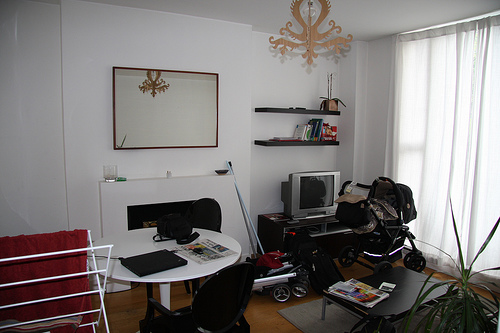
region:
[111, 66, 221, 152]
Mirror above the fireplace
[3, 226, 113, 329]
Towel drying on clothes rack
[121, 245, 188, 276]
Laptop on the table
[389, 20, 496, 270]
Drapes over the window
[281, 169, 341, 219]
Television on a stand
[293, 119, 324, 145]
Books on a shelf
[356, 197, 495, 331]
Green plant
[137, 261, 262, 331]
Chair pushed up to the table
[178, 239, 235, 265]
Newspaper on the table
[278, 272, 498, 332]
Rug on the floor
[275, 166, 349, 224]
silver and black tv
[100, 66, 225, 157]
picture in a brown frame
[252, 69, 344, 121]
black bookshelf with a plant on it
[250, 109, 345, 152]
books lined up on a bookshelf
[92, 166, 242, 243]
fireplace with a white mantle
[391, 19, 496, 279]
sliding glass door covered by a curtain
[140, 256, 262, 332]
chair with a black back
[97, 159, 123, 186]
small jar made of glass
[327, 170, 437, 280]
stroller sitting in the room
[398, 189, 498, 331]
large plant with green leaves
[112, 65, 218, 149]
a mirror on the wall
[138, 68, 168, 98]
object is reflecting in mirror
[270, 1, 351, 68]
object hanging from ceiling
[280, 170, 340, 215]
an old style TV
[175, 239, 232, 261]
newspaper on table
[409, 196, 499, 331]
thin green plant leaves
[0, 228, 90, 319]
the towel is red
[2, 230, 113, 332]
towel rack is white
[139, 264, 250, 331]
the chair is black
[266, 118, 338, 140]
stuff on a shelf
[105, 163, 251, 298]
A white and black fireplace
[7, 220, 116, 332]
A white foldable rack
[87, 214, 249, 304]
A round white table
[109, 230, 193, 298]
A closed laptop on a table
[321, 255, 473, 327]
A black coffee table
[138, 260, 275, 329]
A black desk chair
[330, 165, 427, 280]
A black baby stroller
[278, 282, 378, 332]
An area rug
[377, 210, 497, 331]
Part of a green houseplant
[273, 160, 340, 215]
A grey television turned off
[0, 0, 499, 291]
The walls and ceiling are painted white.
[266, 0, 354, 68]
A decorative light fixture hanging from the ceiling.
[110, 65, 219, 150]
A large mirror with a brown frame.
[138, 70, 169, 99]
A reflection of the light fixture in the mirror.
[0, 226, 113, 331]
A red blanket on a white blanket rack.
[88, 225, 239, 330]
A white table with a round top.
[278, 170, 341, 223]
A gray and black tube television set.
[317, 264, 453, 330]
A small wooden table with metal legs.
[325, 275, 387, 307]
A magazine on the corner of the table.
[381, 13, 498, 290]
Long white drapes on the window.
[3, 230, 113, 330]
the white metal drying rack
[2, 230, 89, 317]
the red hanging towel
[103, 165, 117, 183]
the glass vase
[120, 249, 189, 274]
the black closed laptop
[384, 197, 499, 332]
the long leafy house plant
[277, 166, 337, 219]
an old silver large tv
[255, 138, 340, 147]
a wooden shelf on the wall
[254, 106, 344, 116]
a wooden shelf on the wall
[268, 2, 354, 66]
an odd light fixure hanging from the ceiling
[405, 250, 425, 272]
the wheel of a stroller